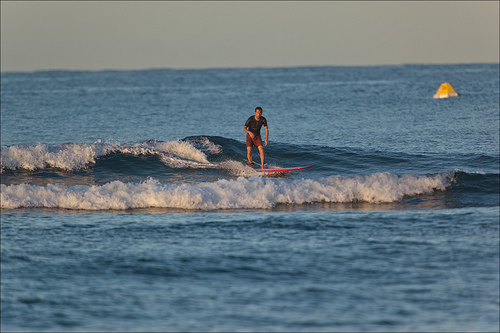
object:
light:
[177, 128, 367, 217]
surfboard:
[251, 164, 309, 173]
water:
[0, 63, 500, 332]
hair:
[253, 106, 265, 110]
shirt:
[244, 115, 267, 137]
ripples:
[0, 63, 500, 332]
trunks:
[246, 135, 261, 147]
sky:
[0, 0, 498, 72]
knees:
[244, 144, 254, 151]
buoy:
[431, 81, 458, 99]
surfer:
[241, 106, 268, 170]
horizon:
[0, 62, 500, 76]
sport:
[241, 106, 310, 173]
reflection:
[160, 174, 362, 211]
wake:
[155, 150, 242, 175]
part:
[334, 261, 414, 304]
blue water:
[0, 63, 500, 331]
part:
[64, 237, 128, 278]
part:
[365, 171, 423, 203]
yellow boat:
[430, 83, 459, 99]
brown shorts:
[245, 133, 261, 144]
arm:
[263, 118, 269, 140]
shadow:
[206, 135, 500, 186]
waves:
[0, 135, 500, 174]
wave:
[0, 168, 500, 210]